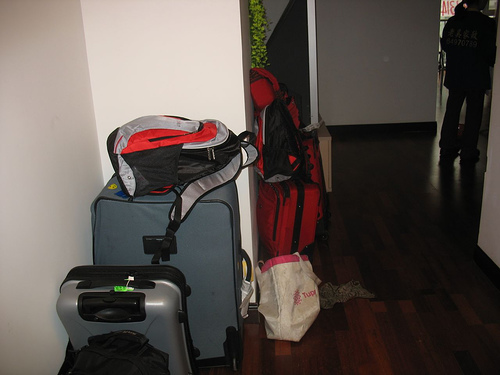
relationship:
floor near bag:
[87, 123, 500, 372] [250, 240, 330, 361]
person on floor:
[439, 2, 496, 159] [87, 123, 500, 372]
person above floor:
[439, 2, 496, 159] [87, 123, 500, 372]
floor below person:
[87, 123, 500, 372] [439, 2, 496, 159]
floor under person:
[87, 123, 500, 372] [439, 2, 496, 159]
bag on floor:
[250, 240, 330, 361] [87, 123, 500, 372]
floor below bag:
[87, 123, 500, 372] [250, 240, 330, 361]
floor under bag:
[87, 123, 500, 372] [250, 240, 330, 361]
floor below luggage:
[87, 123, 500, 372] [56, 95, 249, 374]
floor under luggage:
[87, 123, 500, 372] [56, 95, 249, 374]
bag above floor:
[250, 240, 330, 361] [87, 123, 500, 372]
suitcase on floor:
[57, 261, 196, 373] [335, 137, 429, 365]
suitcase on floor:
[91, 173, 243, 366] [335, 137, 429, 365]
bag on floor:
[254, 252, 319, 341] [335, 137, 429, 365]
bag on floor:
[63, 326, 172, 372] [335, 137, 429, 365]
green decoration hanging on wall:
[244, 0, 273, 67] [93, 0, 245, 124]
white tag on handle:
[239, 275, 259, 317] [236, 248, 256, 281]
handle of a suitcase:
[236, 248, 256, 281] [90, 170, 254, 370]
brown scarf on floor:
[319, 273, 374, 315] [330, 311, 483, 369]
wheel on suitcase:
[221, 350, 244, 370] [91, 173, 241, 363]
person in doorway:
[431, 2, 481, 156] [437, 3, 482, 130]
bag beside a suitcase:
[66, 330, 174, 375] [54, 262, 195, 372]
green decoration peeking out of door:
[249, 0, 269, 67] [245, 0, 323, 127]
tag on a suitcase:
[113, 283, 133, 298] [54, 262, 195, 372]